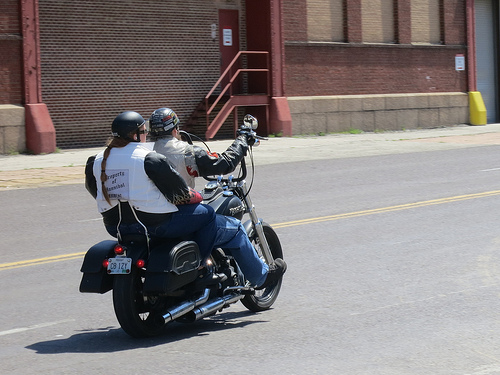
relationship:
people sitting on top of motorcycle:
[84, 109, 229, 292] [78, 114, 287, 340]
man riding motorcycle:
[148, 105, 286, 290] [78, 114, 287, 340]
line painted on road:
[277, 188, 498, 233] [0, 145, 500, 375]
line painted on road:
[3, 248, 81, 274] [0, 145, 500, 375]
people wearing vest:
[84, 109, 229, 292] [120, 153, 147, 208]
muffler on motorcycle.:
[159, 302, 193, 321] [62, 95, 351, 319]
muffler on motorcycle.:
[208, 291, 232, 313] [62, 95, 351, 319]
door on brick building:
[218, 9, 258, 109] [0, 0, 477, 156]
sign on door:
[222, 28, 233, 46] [208, 0, 255, 92]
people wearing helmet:
[84, 109, 229, 292] [92, 105, 149, 140]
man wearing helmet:
[148, 105, 286, 290] [93, 96, 195, 147]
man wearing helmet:
[148, 105, 286, 290] [147, 94, 192, 155]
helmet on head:
[147, 94, 192, 155] [108, 122, 150, 150]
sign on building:
[455, 54, 466, 71] [3, 0, 490, 147]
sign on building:
[222, 27, 234, 46] [3, 0, 490, 147]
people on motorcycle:
[94, 106, 220, 220] [94, 172, 300, 330]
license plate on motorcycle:
[105, 253, 132, 272] [108, 114, 280, 294]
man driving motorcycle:
[145, 105, 289, 285] [78, 114, 287, 340]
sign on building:
[449, 50, 471, 75] [279, 0, 482, 92]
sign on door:
[222, 28, 233, 46] [218, 11, 248, 88]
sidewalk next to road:
[0, 123, 498, 190] [2, 150, 497, 373]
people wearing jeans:
[84, 109, 229, 292] [100, 200, 220, 267]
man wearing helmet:
[148, 105, 286, 290] [139, 107, 184, 132]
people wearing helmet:
[84, 109, 229, 292] [97, 109, 142, 136]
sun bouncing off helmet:
[123, 100, 168, 115] [107, 122, 140, 147]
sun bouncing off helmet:
[123, 100, 168, 115] [161, 101, 187, 141]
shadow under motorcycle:
[14, 308, 274, 355] [25, 121, 355, 333]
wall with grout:
[43, 5, 225, 110] [47, 73, 181, 86]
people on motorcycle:
[84, 109, 229, 292] [78, 114, 287, 340]